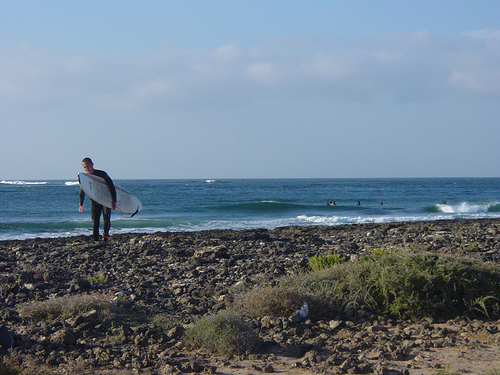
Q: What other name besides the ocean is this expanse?
A: The sea.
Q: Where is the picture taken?
A: A beach.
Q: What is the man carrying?
A: A surfboard.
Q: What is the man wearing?
A: A wetsuit.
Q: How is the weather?
A: Sunny.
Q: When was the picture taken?
A: Morning.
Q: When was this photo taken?
A: Daytime.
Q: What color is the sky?
A: Blue.